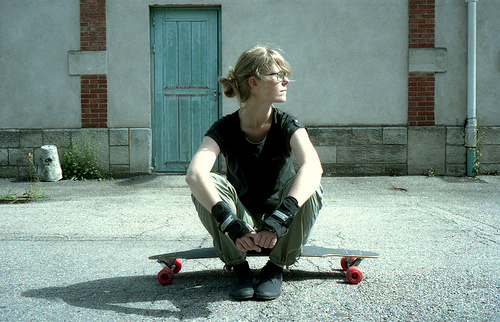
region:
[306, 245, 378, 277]
a skating board on the floor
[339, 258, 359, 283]
two wheels of a skating board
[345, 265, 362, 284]
a red skating wheel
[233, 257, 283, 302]
black shoes of a lady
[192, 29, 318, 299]
a lady seated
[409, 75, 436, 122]
red bricks on the wall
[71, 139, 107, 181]
a green plant near the wall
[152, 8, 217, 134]
a wooden door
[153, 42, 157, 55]
the hinge of a door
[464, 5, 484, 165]
a pipe on the wall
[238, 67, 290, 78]
girl has black glasses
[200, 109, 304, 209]
girl has black shirt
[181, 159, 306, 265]
girl has green pants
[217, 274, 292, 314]
girl has black shoes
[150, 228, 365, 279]
girl sits on skateboard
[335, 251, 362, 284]
red wheels on skateboard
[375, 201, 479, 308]
sidewalk is light grey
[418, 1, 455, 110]
red bricks on wall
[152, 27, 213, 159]
door is light blue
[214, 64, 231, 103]
brown hair tied back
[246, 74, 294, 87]
girl has black glasses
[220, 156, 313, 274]
girl has green pants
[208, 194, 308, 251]
black and grey wristbands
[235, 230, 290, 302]
girl has black shoes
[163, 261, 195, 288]
red wheels on skateboard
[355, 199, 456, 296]
concrete is light grey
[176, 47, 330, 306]
the woman has glasses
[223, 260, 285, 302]
the shoes are black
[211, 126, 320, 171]
the tshirt is black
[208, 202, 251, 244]
the wristband is black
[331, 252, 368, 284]
the wheelsd are red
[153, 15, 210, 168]
the door is blue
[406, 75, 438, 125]
the bricks are red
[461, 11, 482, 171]
the drain pipe is againaist the wall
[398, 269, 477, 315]
the ground is grey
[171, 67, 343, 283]
the woman is sitting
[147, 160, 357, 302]
the woman is on a skateboard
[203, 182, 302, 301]
the woman has black shoes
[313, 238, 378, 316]
the wheels are red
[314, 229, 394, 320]
the skateboard is black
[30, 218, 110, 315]
the cement is cracked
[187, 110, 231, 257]
the woman has short sleeves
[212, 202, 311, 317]
the woman is wearing wristbands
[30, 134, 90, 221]
a stone is by the bushes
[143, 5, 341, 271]
the door is blue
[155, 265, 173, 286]
red wheel on the skate board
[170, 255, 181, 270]
red wheel on the skate board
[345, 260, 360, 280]
red wheel on the skate board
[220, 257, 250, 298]
black shoe on the woman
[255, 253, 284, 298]
black shoe on the woman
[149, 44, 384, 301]
a woman sitting on a skate board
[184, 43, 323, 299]
a woman with blond hair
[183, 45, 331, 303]
a woman wearing glasses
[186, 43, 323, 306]
a woman wearing a black t-shirt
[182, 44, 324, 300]
a woman wearing black sneakers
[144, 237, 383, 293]
a skateboard with red wheels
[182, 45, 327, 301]
a woman wearing wrist guards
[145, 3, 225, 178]
a old wooden door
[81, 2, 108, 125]
bricks on a a building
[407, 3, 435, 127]
bricks on a a building